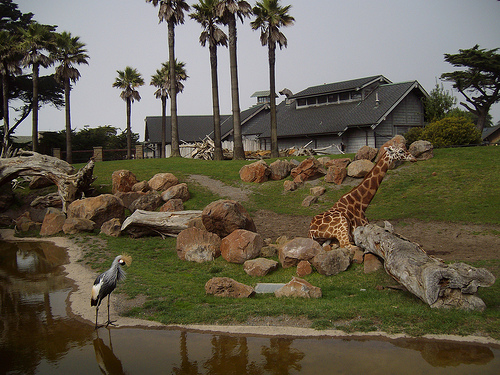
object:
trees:
[249, 1, 290, 156]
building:
[142, 74, 421, 160]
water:
[0, 237, 497, 374]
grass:
[55, 149, 496, 335]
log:
[0, 146, 102, 214]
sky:
[0, 3, 500, 143]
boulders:
[239, 160, 270, 181]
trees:
[191, 0, 229, 156]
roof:
[143, 74, 417, 142]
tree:
[113, 64, 148, 156]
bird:
[92, 255, 134, 327]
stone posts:
[135, 144, 152, 159]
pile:
[184, 130, 225, 162]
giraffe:
[306, 145, 416, 249]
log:
[351, 218, 497, 313]